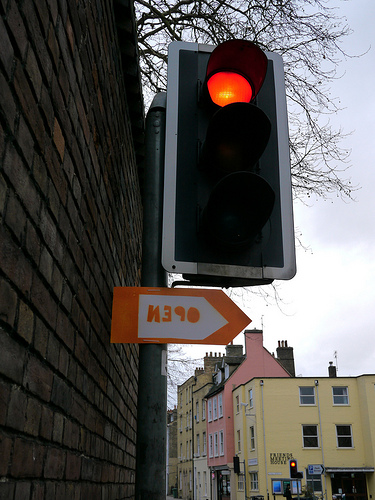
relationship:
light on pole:
[207, 72, 252, 107] [137, 95, 166, 498]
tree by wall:
[133, 0, 356, 210] [0, 0, 140, 278]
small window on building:
[299, 414, 325, 454] [230, 375, 374, 499]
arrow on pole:
[111, 287, 253, 345] [107, 275, 193, 498]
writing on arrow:
[146, 303, 201, 323] [111, 287, 253, 345]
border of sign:
[159, 38, 191, 283] [162, 39, 297, 288]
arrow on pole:
[107, 287, 255, 350] [145, 105, 168, 497]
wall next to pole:
[0, 5, 146, 500] [126, 88, 166, 496]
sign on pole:
[162, 39, 297, 288] [134, 83, 174, 498]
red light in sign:
[208, 72, 258, 106] [162, 39, 297, 288]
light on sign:
[207, 72, 252, 107] [162, 39, 297, 288]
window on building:
[286, 381, 349, 442] [227, 377, 363, 496]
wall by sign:
[13, 5, 145, 492] [162, 39, 297, 288]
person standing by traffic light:
[282, 483, 292, 497] [289, 456, 299, 481]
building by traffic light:
[176, 357, 372, 495] [286, 459, 303, 478]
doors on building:
[326, 469, 369, 497] [227, 377, 363, 496]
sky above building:
[135, 0, 375, 409] [230, 375, 374, 499]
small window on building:
[301, 424, 320, 450] [230, 375, 374, 499]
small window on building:
[287, 382, 322, 406] [234, 377, 362, 489]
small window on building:
[299, 385, 316, 406] [230, 375, 374, 499]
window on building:
[245, 387, 257, 411] [230, 375, 374, 499]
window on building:
[244, 425, 259, 456] [230, 375, 374, 499]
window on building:
[235, 394, 240, 415] [235, 370, 374, 494]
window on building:
[235, 428, 243, 452] [230, 375, 374, 499]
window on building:
[213, 388, 226, 415] [201, 326, 293, 499]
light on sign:
[191, 42, 262, 112] [169, 35, 299, 277]